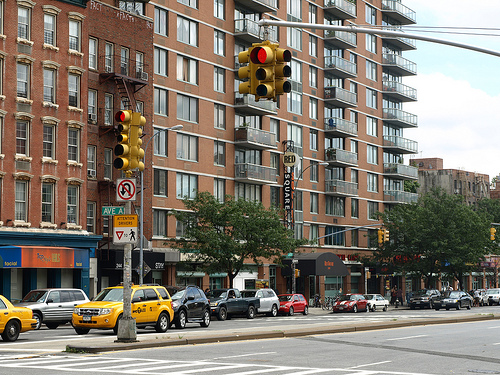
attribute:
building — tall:
[0, 0, 418, 310]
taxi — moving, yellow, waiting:
[74, 281, 175, 333]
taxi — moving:
[0, 295, 38, 342]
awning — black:
[283, 251, 347, 276]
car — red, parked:
[332, 292, 371, 313]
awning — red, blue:
[0, 245, 91, 271]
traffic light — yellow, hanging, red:
[236, 39, 294, 100]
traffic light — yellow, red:
[112, 107, 146, 176]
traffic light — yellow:
[376, 227, 391, 245]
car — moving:
[166, 284, 212, 325]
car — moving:
[432, 289, 476, 311]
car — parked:
[362, 293, 391, 311]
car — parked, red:
[277, 292, 311, 315]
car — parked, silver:
[241, 288, 281, 315]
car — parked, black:
[204, 288, 261, 317]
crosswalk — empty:
[1, 346, 434, 374]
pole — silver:
[118, 174, 138, 341]